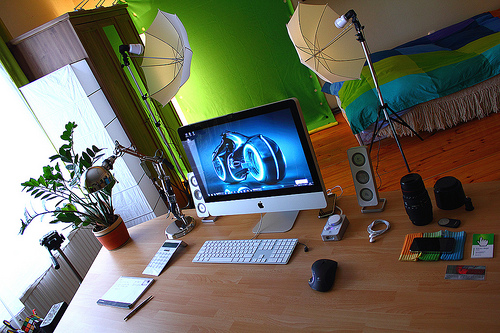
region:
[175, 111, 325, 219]
flat apple computer monitor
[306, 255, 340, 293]
black mouse on a desk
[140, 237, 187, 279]
small solar calculator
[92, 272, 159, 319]
notepad and pen on desk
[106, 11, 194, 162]
professional lights for a photo shoot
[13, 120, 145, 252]
green houseplant on desk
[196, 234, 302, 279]
white keyboard on desk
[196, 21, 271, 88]
green back drop for photo shoot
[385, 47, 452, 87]
geometric bedspread with colors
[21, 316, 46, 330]
rubrics cube that needs to be solved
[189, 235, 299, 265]
mac keyboard for typing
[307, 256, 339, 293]
wireless mouse on the desk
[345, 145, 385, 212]
surround sound system for mac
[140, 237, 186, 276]
business calculator for work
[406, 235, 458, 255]
ipod for relax time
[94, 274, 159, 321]
pen and pad for taking notes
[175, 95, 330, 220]
mac monitor on the desk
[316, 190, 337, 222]
iphone charging on the desk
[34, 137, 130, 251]
small plant for decoration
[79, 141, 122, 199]
head of lamp on the desk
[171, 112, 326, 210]
Monitor is on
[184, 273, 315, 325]
Table is brown color.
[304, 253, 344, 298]
Mouse is black color.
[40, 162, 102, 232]
Leaves are green color.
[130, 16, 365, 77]
Umbrella is white color.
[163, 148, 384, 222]
Speakers on side of the monitor.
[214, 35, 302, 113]
Wall is green color.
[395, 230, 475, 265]
Cell phone is black color.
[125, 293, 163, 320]
Pen is on the table.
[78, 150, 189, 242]
Lamp is silver color.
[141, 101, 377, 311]
A computer on a table.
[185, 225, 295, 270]
A keyboard on a table.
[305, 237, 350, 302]
A mouse on a table.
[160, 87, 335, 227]
A monitor on a table.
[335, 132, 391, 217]
A speaker on the table.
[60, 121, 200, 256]
A desk lamp.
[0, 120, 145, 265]
A little plant on the table.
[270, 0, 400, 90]
An umbrella for lighting a photo shoot.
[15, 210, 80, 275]
A camera.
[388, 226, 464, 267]
A cell phone.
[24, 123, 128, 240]
the plant at the corner of the table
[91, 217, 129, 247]
the plants pot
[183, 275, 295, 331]
top of the wooden desk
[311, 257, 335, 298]
the cordless black mouse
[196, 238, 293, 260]
the cordless keyboard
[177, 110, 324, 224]
the apple monitor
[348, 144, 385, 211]
the computer speaker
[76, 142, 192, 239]
the shiny silver table lamp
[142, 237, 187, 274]
the table calculator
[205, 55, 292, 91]
the green screen